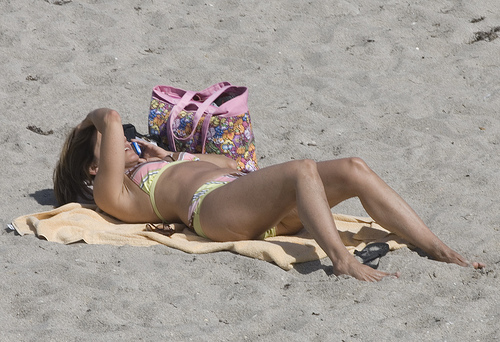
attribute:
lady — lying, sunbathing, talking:
[74, 121, 451, 297]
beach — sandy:
[8, 2, 498, 338]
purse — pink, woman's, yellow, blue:
[158, 88, 249, 150]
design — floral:
[158, 107, 242, 150]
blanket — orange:
[10, 202, 354, 277]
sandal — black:
[351, 244, 386, 268]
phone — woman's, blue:
[121, 121, 152, 163]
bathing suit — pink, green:
[129, 152, 199, 216]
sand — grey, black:
[34, 240, 271, 341]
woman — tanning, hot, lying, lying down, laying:
[57, 113, 392, 242]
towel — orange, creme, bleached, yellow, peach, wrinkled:
[67, 213, 287, 260]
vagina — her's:
[268, 228, 283, 231]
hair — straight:
[52, 135, 93, 212]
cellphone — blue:
[124, 144, 147, 157]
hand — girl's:
[71, 107, 108, 143]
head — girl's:
[68, 108, 135, 187]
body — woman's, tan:
[122, 153, 277, 235]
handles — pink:
[170, 81, 211, 165]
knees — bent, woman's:
[287, 148, 374, 194]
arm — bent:
[75, 107, 144, 194]